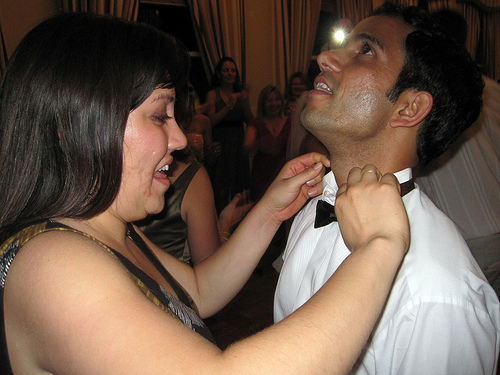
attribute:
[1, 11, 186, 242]
hair — dark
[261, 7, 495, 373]
person — in a room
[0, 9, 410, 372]
woman — touching the man, tall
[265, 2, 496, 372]
man — looking up in the air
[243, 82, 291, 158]
person — in a room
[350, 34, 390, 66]
eye — looking down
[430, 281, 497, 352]
wrinkles — on shirt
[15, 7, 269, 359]
woman — messing with a man's collar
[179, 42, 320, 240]
partiers —  in the background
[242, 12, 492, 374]
person — in a room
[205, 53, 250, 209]
person — background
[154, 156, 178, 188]
mouth — open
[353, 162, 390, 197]
ring — on finger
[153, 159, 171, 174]
teeth — in a row, on top of mouth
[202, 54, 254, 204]
person standing — in a room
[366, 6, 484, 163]
hair — dark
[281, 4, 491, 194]
head — angled up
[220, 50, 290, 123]
people — clapping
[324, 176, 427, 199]
collar — man's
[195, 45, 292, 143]
partyers — group 